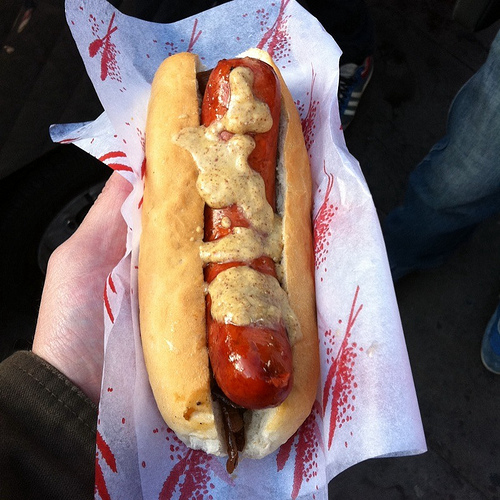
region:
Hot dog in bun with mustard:
[135, 55, 337, 470]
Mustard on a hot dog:
[182, 73, 304, 345]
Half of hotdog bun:
[141, 52, 216, 452]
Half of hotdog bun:
[273, 50, 319, 450]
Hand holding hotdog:
[29, 162, 163, 444]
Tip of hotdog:
[194, 55, 291, 95]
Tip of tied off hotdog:
[227, 359, 308, 423]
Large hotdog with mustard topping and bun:
[120, 47, 334, 460]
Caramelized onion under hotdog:
[205, 402, 262, 475]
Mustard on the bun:
[165, 125, 200, 159]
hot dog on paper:
[127, 55, 342, 492]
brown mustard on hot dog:
[185, 78, 282, 369]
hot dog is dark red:
[183, 44, 344, 459]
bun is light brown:
[141, 67, 203, 412]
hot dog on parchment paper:
[98, 75, 332, 433]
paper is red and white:
[94, 79, 197, 497]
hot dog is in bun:
[197, 93, 297, 428]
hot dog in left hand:
[15, 8, 367, 460]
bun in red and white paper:
[124, 58, 304, 435]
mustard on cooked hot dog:
[177, 60, 314, 381]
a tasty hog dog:
[144, 28, 346, 442]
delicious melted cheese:
[184, 75, 296, 339]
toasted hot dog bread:
[147, 57, 214, 446]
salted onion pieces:
[213, 397, 253, 477]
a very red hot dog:
[206, 329, 304, 426]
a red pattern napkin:
[313, 216, 427, 485]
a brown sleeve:
[3, 349, 91, 497]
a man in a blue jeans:
[399, 28, 496, 368]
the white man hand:
[36, 168, 125, 379]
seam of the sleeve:
[5, 351, 101, 434]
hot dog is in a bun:
[170, 57, 304, 392]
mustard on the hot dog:
[177, 46, 282, 376]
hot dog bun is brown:
[144, 30, 349, 475]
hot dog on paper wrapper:
[60, 0, 478, 486]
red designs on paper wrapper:
[61, 20, 393, 486]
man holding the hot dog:
[0, 108, 224, 495]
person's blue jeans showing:
[397, 20, 497, 332]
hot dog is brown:
[192, 58, 311, 463]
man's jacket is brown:
[0, 324, 127, 496]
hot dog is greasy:
[194, 299, 331, 406]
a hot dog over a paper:
[129, 34, 334, 476]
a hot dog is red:
[196, 54, 297, 419]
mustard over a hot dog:
[183, 60, 310, 361]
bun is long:
[129, 41, 333, 473]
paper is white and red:
[54, 37, 431, 498]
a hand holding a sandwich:
[7, 102, 184, 479]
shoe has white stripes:
[337, 54, 379, 128]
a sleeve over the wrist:
[0, 341, 116, 491]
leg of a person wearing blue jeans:
[393, 40, 498, 308]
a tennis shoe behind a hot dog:
[339, 54, 388, 131]